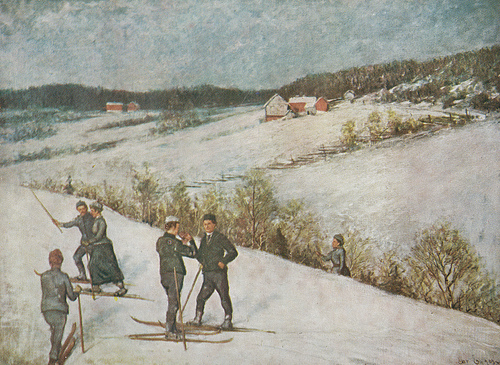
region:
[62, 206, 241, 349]
five people are skiing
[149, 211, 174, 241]
man wears white cap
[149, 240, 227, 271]
men wear dark suits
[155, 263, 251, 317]
men wear dark pants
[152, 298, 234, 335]
men wear dark boots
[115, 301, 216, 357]
people have brown skis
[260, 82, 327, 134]
large red barn in distance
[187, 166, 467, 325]
hill with bare trees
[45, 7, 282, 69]
sky has white clouds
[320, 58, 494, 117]
mountain with trees in distance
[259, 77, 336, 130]
red and white barn in the distance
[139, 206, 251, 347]
two men talking in the snow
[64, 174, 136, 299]
a man and a woman walking across the snow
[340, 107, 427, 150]
trees in the distance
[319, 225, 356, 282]
a woman walking up the hill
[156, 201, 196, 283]
a man wearing a hat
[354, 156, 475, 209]
a field covered in snow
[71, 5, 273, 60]
a cloudy sky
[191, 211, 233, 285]
a man with his hands in his pockets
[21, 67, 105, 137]
a mountain in the distance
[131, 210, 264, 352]
Two persons on skis conversing.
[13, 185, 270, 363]
Five illustrated persons on skis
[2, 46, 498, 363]
Painting of rural scene with snow and people on skis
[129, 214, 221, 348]
Man on skis with a white hat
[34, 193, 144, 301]
Vintage painting of man and woman on skis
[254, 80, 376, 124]
Old-style farm in snow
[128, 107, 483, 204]
Snow fence across snowy field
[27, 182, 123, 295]
Man motioning with ski pole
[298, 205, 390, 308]
Woman climbing snow bank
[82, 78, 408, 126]
Rural scene of multiple farms in snow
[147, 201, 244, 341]
Two men standing next to each other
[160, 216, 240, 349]
Two men wearing wooden skis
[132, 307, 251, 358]
Two pairs of wooden skis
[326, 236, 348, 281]
Woman wearing period clothing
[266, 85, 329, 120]
Three red houses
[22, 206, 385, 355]
Snow covered mound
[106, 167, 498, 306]
Row of sparsely covered trees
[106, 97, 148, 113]
Two red houses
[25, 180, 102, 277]
A man pointing with a wooden ski pole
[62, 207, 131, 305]
A man and a woman skiing together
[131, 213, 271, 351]
painting of men on skis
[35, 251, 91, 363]
back of a person on skis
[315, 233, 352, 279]
a woman coming up a mountain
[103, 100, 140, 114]
small red houses in the distance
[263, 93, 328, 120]
collection of red buildings in the distance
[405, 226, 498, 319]
a green and brown bush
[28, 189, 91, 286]
a man on skiis pointing a pole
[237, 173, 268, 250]
a small tree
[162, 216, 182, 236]
a man with a hat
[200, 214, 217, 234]
a man's head with a hat